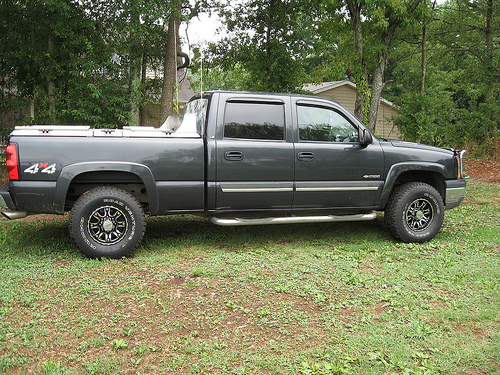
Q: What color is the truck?
A: Grey.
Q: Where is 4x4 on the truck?
A: By the tail light.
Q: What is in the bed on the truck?
A: Chrome Toolboxes.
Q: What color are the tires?
A: Black.